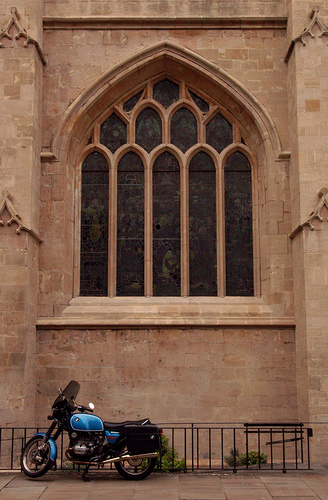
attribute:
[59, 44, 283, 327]
arched window — stunning large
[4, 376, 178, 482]
motorcycle — blue and black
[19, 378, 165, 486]
motorcycle — face shield, blue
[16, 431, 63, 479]
motorcycle — front wheel 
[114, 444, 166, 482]
motorcycle — back wheel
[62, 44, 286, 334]
window — large , brick wall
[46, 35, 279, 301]
window — large, brick wall 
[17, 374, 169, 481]
motorcycle — black box, two mirrors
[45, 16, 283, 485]
building — window 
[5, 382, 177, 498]
motorcycle — blue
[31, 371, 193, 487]
motorcycle — blue